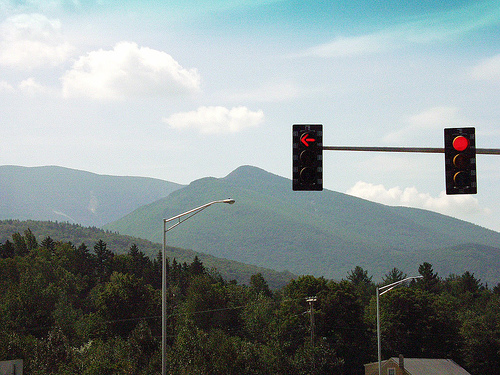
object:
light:
[290, 124, 323, 190]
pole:
[159, 217, 167, 373]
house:
[364, 353, 469, 374]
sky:
[198, 26, 269, 67]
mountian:
[53, 164, 103, 205]